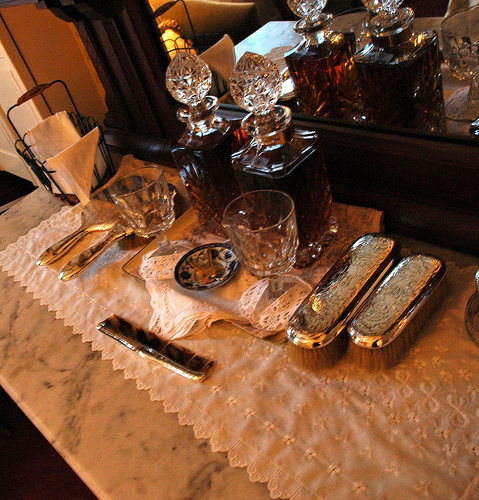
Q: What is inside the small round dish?
A: Keys.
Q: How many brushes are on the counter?
A: Three.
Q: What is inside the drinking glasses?
A: Nothing.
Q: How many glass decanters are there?
A: Two.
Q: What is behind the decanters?
A: A mirror.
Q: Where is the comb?
A: In front of the tray.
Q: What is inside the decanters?
A: Liquid.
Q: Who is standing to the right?
A: No one.